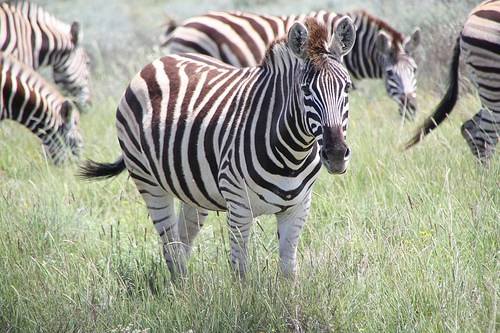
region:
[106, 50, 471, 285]
zebra is black and white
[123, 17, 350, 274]
black and white striped zebra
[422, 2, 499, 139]
black and white striped zebra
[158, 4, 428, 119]
black and white striped zebra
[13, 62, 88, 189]
black and white striped zebra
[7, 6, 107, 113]
black and white striped zebra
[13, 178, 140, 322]
green and tan grass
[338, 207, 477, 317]
green and tan grass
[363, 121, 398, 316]
green and tan grass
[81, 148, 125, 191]
black zebra tail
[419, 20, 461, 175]
black zebra tail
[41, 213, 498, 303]
grass is long and green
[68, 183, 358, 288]
grass is long and green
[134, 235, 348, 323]
grass is long and green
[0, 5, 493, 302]
Five zebras in a field.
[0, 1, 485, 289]
The zebras are black and white.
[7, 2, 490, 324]
Photo taken in the morning.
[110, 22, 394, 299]
One zebra looking at the camera.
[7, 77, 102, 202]
Zebra eating the grass.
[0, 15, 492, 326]
No giraffes shown.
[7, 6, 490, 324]
No people pictured in the photo.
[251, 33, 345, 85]
Zebra with a mohawk.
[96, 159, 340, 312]
The zebra has four legs.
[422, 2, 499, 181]
One zebra exiting the photo.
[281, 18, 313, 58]
ear of a zebra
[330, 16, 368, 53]
ear of a zebra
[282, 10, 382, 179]
head of a zebra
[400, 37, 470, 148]
tail of a zebra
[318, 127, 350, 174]
nose of a zebra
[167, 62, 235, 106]
black and white stripes on a zebra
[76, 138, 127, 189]
tail of a zebra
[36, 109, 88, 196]
a zebra eating grass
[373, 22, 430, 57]
ears of a zebra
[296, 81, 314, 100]
eye of a zebra